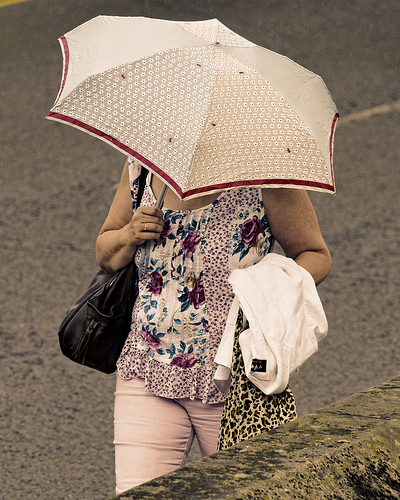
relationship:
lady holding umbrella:
[58, 155, 333, 496] [54, 13, 355, 203]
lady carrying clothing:
[58, 155, 333, 496] [212, 253, 328, 396]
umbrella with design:
[54, 13, 355, 203] [54, 15, 328, 184]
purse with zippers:
[66, 271, 138, 369] [104, 271, 117, 294]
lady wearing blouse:
[58, 155, 333, 496] [115, 156, 275, 405]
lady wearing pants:
[58, 155, 333, 496] [111, 366, 225, 497]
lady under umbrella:
[58, 155, 333, 496] [54, 13, 355, 203]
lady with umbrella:
[58, 155, 333, 496] [54, 13, 355, 203]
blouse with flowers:
[121, 174, 251, 403] [135, 212, 270, 370]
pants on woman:
[115, 394, 187, 463] [116, 160, 291, 280]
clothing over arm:
[212, 253, 328, 396] [259, 188, 333, 287]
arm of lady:
[259, 188, 333, 287] [58, 155, 333, 496]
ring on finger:
[142, 222, 148, 233] [135, 222, 166, 232]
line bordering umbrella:
[43, 31, 340, 203] [54, 13, 355, 203]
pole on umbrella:
[142, 182, 167, 276] [54, 13, 355, 203]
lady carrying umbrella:
[47, 29, 360, 427] [44, 14, 339, 281]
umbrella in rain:
[44, 14, 339, 281] [1, 2, 398, 498]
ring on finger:
[144, 222, 147, 231] [133, 222, 163, 231]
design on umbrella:
[43, 14, 339, 201] [54, 13, 355, 203]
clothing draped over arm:
[221, 264, 327, 396] [261, 188, 337, 333]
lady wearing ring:
[58, 155, 333, 496] [144, 222, 147, 231]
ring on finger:
[144, 222, 147, 231] [136, 221, 163, 231]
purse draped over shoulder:
[58, 166, 152, 375] [121, 150, 161, 188]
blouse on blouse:
[115, 156, 275, 405] [124, 158, 281, 373]